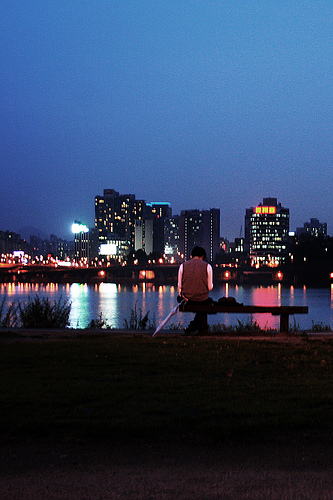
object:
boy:
[176, 248, 214, 333]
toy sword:
[153, 302, 183, 337]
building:
[64, 188, 253, 282]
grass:
[50, 360, 216, 428]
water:
[0, 281, 332, 329]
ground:
[218, 118, 238, 137]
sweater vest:
[180, 258, 207, 299]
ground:
[204, 133, 225, 162]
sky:
[9, 69, 332, 189]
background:
[6, 9, 328, 244]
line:
[91, 278, 124, 329]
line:
[61, 270, 93, 331]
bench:
[180, 303, 308, 332]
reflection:
[2, 280, 329, 328]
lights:
[2, 198, 332, 280]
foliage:
[19, 294, 71, 328]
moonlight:
[1, 3, 332, 187]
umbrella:
[152, 296, 189, 336]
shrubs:
[0, 293, 16, 330]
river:
[0, 273, 329, 329]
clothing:
[210, 294, 244, 306]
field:
[2, 340, 330, 497]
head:
[190, 244, 207, 259]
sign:
[71, 218, 90, 235]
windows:
[252, 199, 278, 214]